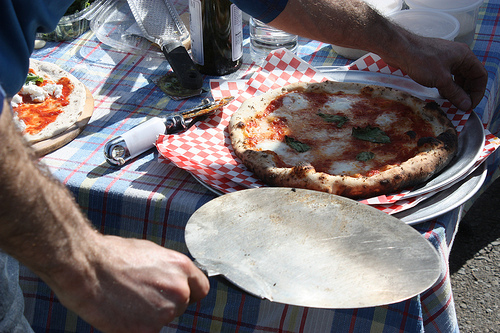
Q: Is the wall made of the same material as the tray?
A: No, the wall is made of cement and the tray is made of metal.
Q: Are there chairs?
A: No, there are no chairs.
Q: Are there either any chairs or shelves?
A: No, there are no chairs or shelves.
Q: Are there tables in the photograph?
A: Yes, there is a table.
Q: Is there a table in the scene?
A: Yes, there is a table.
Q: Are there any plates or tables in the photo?
A: Yes, there is a table.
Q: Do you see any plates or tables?
A: Yes, there is a table.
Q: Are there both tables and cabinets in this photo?
A: No, there is a table but no cabinets.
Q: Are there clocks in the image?
A: No, there are no clocks.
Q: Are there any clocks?
A: No, there are no clocks.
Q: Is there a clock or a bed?
A: No, there are no clocks or beds.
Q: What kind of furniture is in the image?
A: The furniture is a table.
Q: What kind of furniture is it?
A: The piece of furniture is a table.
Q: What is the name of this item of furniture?
A: This is a table.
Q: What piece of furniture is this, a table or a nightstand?
A: This is a table.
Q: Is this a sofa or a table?
A: This is a table.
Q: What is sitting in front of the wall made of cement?
A: The table is sitting in front of the wall.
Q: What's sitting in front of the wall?
A: The table is sitting in front of the wall.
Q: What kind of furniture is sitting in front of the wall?
A: The piece of furniture is a table.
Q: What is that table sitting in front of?
A: The table is sitting in front of the wall.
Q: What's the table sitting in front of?
A: The table is sitting in front of the wall.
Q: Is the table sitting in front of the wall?
A: Yes, the table is sitting in front of the wall.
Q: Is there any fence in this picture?
A: No, there are no fences.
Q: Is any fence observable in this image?
A: No, there are no fences.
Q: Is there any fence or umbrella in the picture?
A: No, there are no fences or umbrellas.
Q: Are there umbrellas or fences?
A: No, there are no fences or umbrellas.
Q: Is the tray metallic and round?
A: Yes, the tray is metallic and round.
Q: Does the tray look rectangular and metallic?
A: No, the tray is metallic but round.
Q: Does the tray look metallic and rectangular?
A: No, the tray is metallic but round.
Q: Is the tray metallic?
A: Yes, the tray is metallic.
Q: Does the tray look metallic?
A: Yes, the tray is metallic.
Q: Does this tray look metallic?
A: Yes, the tray is metallic.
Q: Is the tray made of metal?
A: Yes, the tray is made of metal.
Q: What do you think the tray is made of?
A: The tray is made of metal.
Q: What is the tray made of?
A: The tray is made of metal.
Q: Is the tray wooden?
A: No, the tray is metallic.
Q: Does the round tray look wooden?
A: No, the tray is metallic.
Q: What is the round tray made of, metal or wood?
A: The tray is made of metal.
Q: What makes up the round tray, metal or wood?
A: The tray is made of metal.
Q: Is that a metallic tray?
A: Yes, that is a metallic tray.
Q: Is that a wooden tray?
A: No, that is a metallic tray.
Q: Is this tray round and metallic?
A: Yes, the tray is round and metallic.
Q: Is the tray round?
A: Yes, the tray is round.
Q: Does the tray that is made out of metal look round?
A: Yes, the tray is round.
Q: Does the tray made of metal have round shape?
A: Yes, the tray is round.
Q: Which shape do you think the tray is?
A: The tray is round.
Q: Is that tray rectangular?
A: No, the tray is round.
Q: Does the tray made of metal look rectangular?
A: No, the tray is round.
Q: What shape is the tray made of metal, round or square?
A: The tray is round.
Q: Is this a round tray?
A: Yes, this is a round tray.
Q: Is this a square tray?
A: No, this is a round tray.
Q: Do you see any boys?
A: No, there are no boys.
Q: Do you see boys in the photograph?
A: No, there are no boys.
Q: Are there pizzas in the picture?
A: Yes, there is a pizza.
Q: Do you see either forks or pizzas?
A: Yes, there is a pizza.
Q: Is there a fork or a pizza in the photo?
A: Yes, there is a pizza.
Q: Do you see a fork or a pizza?
A: Yes, there is a pizza.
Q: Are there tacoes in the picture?
A: No, there are no tacoes.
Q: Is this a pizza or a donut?
A: This is a pizza.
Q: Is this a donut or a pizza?
A: This is a pizza.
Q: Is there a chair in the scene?
A: No, there are no chairs.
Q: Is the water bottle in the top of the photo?
A: Yes, the water bottle is in the top of the image.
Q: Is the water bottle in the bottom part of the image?
A: No, the water bottle is in the top of the image.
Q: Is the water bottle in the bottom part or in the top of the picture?
A: The water bottle is in the top of the image.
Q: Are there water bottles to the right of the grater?
A: Yes, there is a water bottle to the right of the grater.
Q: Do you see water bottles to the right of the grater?
A: Yes, there is a water bottle to the right of the grater.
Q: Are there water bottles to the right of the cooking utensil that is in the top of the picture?
A: Yes, there is a water bottle to the right of the grater.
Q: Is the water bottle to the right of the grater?
A: Yes, the water bottle is to the right of the grater.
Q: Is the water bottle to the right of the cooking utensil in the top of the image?
A: Yes, the water bottle is to the right of the grater.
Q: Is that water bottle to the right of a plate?
A: No, the water bottle is to the right of the grater.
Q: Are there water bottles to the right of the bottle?
A: Yes, there is a water bottle to the right of the bottle.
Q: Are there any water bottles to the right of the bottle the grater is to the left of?
A: Yes, there is a water bottle to the right of the bottle.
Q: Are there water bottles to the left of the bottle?
A: No, the water bottle is to the right of the bottle.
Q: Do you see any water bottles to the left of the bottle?
A: No, the water bottle is to the right of the bottle.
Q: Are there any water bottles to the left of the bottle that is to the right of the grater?
A: No, the water bottle is to the right of the bottle.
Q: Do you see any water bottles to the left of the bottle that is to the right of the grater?
A: No, the water bottle is to the right of the bottle.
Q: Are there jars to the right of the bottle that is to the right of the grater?
A: No, there is a water bottle to the right of the bottle.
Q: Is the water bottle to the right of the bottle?
A: Yes, the water bottle is to the right of the bottle.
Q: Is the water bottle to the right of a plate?
A: No, the water bottle is to the right of the bottle.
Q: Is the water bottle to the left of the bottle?
A: No, the water bottle is to the right of the bottle.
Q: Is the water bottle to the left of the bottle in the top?
A: No, the water bottle is to the right of the bottle.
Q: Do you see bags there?
A: No, there are no bags.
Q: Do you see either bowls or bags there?
A: No, there are no bags or bowls.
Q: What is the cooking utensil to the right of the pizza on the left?
A: The cooking utensil is a pizza pan.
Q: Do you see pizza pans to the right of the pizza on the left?
A: Yes, there is a pizza pan to the right of the pizza.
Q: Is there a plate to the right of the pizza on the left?
A: No, there is a pizza pan to the right of the pizza.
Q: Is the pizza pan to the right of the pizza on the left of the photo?
A: Yes, the pizza pan is to the right of the pizza.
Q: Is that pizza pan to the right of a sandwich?
A: No, the pizza pan is to the right of the pizza.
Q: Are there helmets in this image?
A: No, there are no helmets.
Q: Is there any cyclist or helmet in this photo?
A: No, there are no helmets or cyclists.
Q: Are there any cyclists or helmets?
A: No, there are no helmets or cyclists.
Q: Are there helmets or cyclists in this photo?
A: No, there are no helmets or cyclists.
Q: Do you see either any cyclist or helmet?
A: No, there are no helmets or cyclists.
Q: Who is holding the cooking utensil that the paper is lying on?
A: The man is holding the pizza pan.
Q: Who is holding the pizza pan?
A: The man is holding the pizza pan.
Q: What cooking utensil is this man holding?
A: The man is holding the pizza pan.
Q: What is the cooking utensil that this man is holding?
A: The cooking utensil is a pizza pan.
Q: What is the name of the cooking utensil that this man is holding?
A: The cooking utensil is a pizza pan.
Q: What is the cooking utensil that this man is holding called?
A: The cooking utensil is a pizza pan.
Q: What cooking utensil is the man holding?
A: The man is holding the pizza pan.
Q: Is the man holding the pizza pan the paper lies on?
A: Yes, the man is holding the pizza pan.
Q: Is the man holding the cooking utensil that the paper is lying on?
A: Yes, the man is holding the pizza pan.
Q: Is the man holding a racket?
A: No, the man is holding the pizza pan.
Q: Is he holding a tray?
A: Yes, the man is holding a tray.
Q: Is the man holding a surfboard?
A: No, the man is holding a tray.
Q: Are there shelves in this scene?
A: No, there are no shelves.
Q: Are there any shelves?
A: No, there are no shelves.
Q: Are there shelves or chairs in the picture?
A: No, there are no shelves or chairs.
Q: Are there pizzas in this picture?
A: Yes, there is a pizza.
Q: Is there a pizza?
A: Yes, there is a pizza.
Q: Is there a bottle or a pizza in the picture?
A: Yes, there is a pizza.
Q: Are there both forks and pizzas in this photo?
A: No, there is a pizza but no forks.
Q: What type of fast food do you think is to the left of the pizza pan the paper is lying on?
A: The food is a pizza.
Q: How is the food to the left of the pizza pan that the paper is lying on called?
A: The food is a pizza.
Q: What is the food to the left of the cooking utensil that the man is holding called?
A: The food is a pizza.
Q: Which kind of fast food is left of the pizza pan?
A: The food is a pizza.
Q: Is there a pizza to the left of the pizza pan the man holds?
A: Yes, there is a pizza to the left of the pizza pan.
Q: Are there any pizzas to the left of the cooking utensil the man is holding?
A: Yes, there is a pizza to the left of the pizza pan.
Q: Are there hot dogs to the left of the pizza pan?
A: No, there is a pizza to the left of the pizza pan.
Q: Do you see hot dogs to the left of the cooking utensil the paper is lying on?
A: No, there is a pizza to the left of the pizza pan.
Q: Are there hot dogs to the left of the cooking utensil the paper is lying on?
A: No, there is a pizza to the left of the pizza pan.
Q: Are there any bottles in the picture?
A: Yes, there is a bottle.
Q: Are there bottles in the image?
A: Yes, there is a bottle.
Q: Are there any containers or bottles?
A: Yes, there is a bottle.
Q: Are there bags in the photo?
A: No, there are no bags.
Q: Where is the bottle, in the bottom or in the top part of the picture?
A: The bottle is in the top of the image.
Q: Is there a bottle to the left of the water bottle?
A: Yes, there is a bottle to the left of the water bottle.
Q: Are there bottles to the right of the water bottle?
A: No, the bottle is to the left of the water bottle.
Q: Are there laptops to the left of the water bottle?
A: No, there is a bottle to the left of the water bottle.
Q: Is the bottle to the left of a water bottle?
A: Yes, the bottle is to the left of a water bottle.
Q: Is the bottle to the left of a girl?
A: No, the bottle is to the left of a water bottle.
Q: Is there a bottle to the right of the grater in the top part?
A: Yes, there is a bottle to the right of the grater.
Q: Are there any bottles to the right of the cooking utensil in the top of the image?
A: Yes, there is a bottle to the right of the grater.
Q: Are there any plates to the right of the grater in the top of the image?
A: No, there is a bottle to the right of the grater.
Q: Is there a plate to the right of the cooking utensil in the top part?
A: No, there is a bottle to the right of the grater.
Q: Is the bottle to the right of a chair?
A: No, the bottle is to the right of the grater.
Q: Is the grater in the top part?
A: Yes, the grater is in the top of the image.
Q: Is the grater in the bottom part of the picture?
A: No, the grater is in the top of the image.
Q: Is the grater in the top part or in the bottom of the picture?
A: The grater is in the top of the image.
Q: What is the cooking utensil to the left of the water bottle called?
A: The cooking utensil is a grater.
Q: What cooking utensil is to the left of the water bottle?
A: The cooking utensil is a grater.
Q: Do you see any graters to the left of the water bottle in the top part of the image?
A: Yes, there is a grater to the left of the water bottle.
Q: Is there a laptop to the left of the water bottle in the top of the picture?
A: No, there is a grater to the left of the water bottle.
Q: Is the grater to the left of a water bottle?
A: Yes, the grater is to the left of a water bottle.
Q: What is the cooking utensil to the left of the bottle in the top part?
A: The cooking utensil is a grater.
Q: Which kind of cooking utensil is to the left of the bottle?
A: The cooking utensil is a grater.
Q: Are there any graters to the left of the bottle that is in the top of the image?
A: Yes, there is a grater to the left of the bottle.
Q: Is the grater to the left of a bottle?
A: Yes, the grater is to the left of a bottle.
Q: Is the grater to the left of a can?
A: No, the grater is to the left of a bottle.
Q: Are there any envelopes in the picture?
A: No, there are no envelopes.